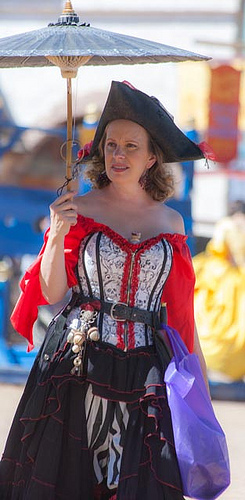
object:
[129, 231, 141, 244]
bottle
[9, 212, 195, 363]
shirt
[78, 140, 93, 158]
flowers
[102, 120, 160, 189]
head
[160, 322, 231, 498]
bag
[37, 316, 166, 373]
hip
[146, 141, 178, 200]
hair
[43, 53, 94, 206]
bamboo handle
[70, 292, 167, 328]
belt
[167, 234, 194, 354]
red sleeve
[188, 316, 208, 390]
arm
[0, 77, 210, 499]
woman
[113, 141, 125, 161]
nose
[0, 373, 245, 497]
ground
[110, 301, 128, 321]
metal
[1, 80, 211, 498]
girl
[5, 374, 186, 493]
lace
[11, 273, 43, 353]
fabric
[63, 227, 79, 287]
sleeve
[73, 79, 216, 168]
hat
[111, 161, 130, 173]
mouth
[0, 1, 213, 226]
parisol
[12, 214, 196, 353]
corset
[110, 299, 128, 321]
silver buckle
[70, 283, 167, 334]
waist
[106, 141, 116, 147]
eyes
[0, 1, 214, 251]
umbrella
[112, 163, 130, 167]
lips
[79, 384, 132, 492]
pattern skirt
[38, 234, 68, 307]
forearm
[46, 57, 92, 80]
umbrella opener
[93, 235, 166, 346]
cloths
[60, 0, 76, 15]
bamboo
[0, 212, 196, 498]
costume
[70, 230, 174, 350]
bodice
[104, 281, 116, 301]
skull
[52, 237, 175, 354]
torso